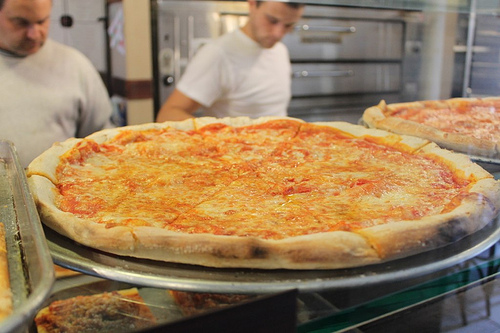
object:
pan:
[30, 225, 499, 293]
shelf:
[0, 134, 500, 310]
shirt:
[0, 36, 112, 164]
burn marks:
[207, 237, 270, 261]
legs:
[452, 249, 472, 325]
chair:
[450, 242, 493, 326]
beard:
[245, 10, 281, 49]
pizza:
[19, 114, 499, 269]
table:
[0, 123, 498, 330]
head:
[0, 0, 54, 56]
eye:
[11, 16, 29, 26]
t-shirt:
[172, 25, 299, 116]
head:
[243, 0, 299, 49]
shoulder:
[173, 33, 239, 109]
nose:
[271, 25, 283, 39]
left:
[0, 3, 159, 331]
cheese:
[101, 174, 221, 219]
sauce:
[276, 182, 315, 196]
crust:
[129, 222, 376, 267]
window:
[3, 268, 497, 329]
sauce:
[47, 305, 95, 324]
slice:
[42, 281, 157, 331]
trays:
[453, 2, 493, 32]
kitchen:
[5, 0, 495, 330]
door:
[284, 60, 409, 99]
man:
[2, 1, 124, 191]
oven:
[161, 3, 439, 117]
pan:
[1, 131, 61, 330]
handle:
[293, 67, 355, 79]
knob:
[163, 75, 176, 86]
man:
[151, 4, 301, 133]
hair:
[245, 0, 303, 14]